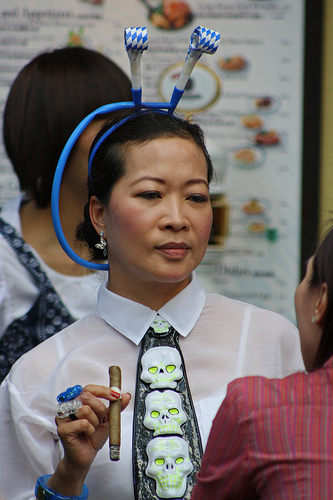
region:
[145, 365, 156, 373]
yellow colored skeletin eye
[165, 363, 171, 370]
yellow colored skeletin eye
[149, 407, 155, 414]
yellow colored skeletin eye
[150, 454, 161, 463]
yellow colored skeletin eye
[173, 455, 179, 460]
yellow colored skeletin eye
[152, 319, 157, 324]
yellow colored skeletin eye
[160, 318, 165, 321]
yellow colored skeletin eye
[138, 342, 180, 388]
white colored skeleton head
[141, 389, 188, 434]
white colored skeleton head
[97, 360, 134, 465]
woman holding a cigar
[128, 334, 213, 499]
Tie with skulls on it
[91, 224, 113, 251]
woman wearing earrings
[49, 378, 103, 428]
woman wearing two hand rings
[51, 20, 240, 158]
woman with party favors on her head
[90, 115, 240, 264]
woman with black hair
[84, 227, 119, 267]
woman wearing earrings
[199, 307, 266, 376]
woman wearing a white shirt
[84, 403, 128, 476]
the cigar is brown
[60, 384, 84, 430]
these are some rings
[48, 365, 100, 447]
the rings are blue and white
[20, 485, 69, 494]
this is a bracelet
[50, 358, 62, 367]
this is a white shirt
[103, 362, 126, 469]
The brown cigar.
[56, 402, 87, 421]
The clear skeleton bracelet.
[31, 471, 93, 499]
The blue bracelet.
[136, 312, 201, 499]
The black skeleton tie.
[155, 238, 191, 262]
The woman with the skeleton ties mouth.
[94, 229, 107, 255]
Left earrings.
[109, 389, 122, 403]
The red pointer nail.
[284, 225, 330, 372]
The back of a womans head.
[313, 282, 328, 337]
The woman's left ear.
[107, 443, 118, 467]
The ashes on the cigar.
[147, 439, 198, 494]
A white skul with green eyes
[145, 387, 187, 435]
A white skul with green eyes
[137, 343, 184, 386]
A white skul with green eyes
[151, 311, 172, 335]
A white skul with green eyes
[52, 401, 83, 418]
A shiny clear ring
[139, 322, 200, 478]
A skull design tie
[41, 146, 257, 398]
A woman in a white shirt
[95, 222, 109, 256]
A beautiful silver earing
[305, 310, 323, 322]
A beautiful silver earing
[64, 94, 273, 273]
a woman smoking a cigar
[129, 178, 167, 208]
an eye on the woman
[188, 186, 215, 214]
an eye on the woman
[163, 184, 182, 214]
a nose on the woman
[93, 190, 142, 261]
an ear on the woman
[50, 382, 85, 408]
a ring on the finger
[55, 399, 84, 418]
a ring on the finger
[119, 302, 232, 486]
a tie on the shirt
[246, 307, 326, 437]
a woman wearing a shirt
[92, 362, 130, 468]
A cigar in the lady hand.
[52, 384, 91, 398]
The ring is blue.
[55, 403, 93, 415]
The ring is clear.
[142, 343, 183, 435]
Skulls on the tie.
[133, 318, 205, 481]
The woman is wearing a tie.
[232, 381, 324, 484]
The shirt is red plaided.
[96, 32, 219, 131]
The lady is wearing a blue hat.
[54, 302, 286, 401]
The shirt is white.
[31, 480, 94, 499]
The bracelet is blue.